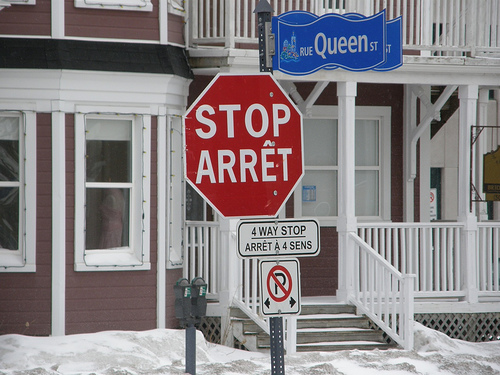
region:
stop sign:
[136, 77, 428, 323]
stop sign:
[171, 92, 340, 251]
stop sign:
[169, 60, 282, 212]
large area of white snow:
[25, 320, 124, 365]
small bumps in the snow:
[61, 350, 122, 373]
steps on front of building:
[300, 289, 382, 360]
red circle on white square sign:
[262, 263, 317, 313]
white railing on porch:
[329, 219, 425, 349]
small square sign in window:
[296, 179, 334, 205]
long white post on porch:
[329, 80, 369, 285]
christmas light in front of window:
[74, 98, 166, 269]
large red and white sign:
[183, 70, 330, 217]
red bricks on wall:
[85, 285, 158, 320]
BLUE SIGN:
[272, 10, 410, 76]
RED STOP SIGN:
[175, 70, 327, 215]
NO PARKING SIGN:
[257, 257, 307, 322]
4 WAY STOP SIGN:
[230, 215, 315, 255]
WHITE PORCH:
[332, 131, 492, 351]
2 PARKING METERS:
[165, 275, 212, 370]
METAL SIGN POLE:
[263, 311, 293, 371]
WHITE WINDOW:
[77, 95, 148, 280]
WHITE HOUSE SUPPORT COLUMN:
[335, 80, 360, 301]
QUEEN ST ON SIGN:
[273, 14, 419, 75]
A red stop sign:
[173, 66, 313, 224]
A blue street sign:
[259, 7, 415, 81]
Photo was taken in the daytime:
[8, 3, 491, 374]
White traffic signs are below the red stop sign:
[172, 68, 327, 318]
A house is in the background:
[0, 0, 497, 330]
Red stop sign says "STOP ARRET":
[163, 68, 316, 221]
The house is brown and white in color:
[6, 4, 173, 326]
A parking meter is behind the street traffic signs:
[163, 266, 214, 373]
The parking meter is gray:
[161, 268, 215, 373]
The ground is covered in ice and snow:
[1, 316, 498, 372]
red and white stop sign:
[142, 68, 317, 214]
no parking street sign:
[244, 262, 316, 318]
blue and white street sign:
[231, 18, 425, 68]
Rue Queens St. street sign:
[275, 22, 392, 83]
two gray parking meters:
[160, 298, 236, 333]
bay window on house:
[2, 59, 188, 306]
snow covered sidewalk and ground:
[59, 322, 262, 372]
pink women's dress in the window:
[95, 195, 154, 251]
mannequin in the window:
[88, 186, 141, 264]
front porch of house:
[327, 217, 498, 304]